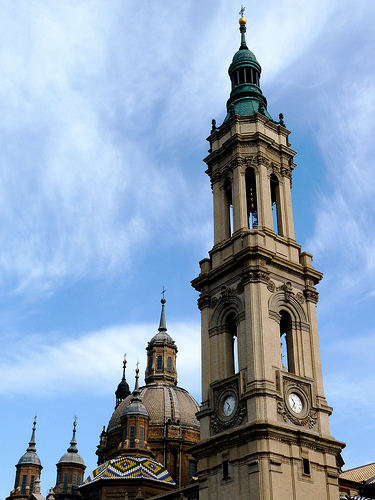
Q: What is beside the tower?
A: A large dome.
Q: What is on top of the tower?
A: A steeple.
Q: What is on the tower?
A: A clock.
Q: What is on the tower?
A: A clock.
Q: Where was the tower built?
A: In Europe.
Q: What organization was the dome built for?
A: The Christian church.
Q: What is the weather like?
A: The weather is hospitable.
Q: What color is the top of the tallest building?
A: Blue.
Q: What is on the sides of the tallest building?
A: Clock.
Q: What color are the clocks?
A: White.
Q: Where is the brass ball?
A: On top the spire.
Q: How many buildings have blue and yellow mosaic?
A: One.